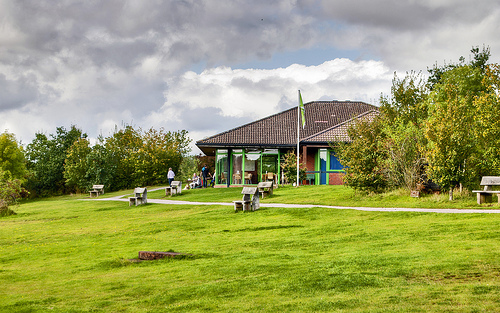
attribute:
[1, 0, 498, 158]
cloud — thin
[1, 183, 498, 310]
grass — green, bright, bright green, vibrant green, healthy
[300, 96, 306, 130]
flag — drooping down, raised, green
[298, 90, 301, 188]
flag pole — white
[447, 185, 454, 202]
tree trunk — sticking out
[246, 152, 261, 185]
glass — reflective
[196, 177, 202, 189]
person — sitting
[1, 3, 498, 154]
sky — blue, mostly cloudy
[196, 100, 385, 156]
roof — brown, tiled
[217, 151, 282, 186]
patio porch — green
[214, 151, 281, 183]
green window — framed